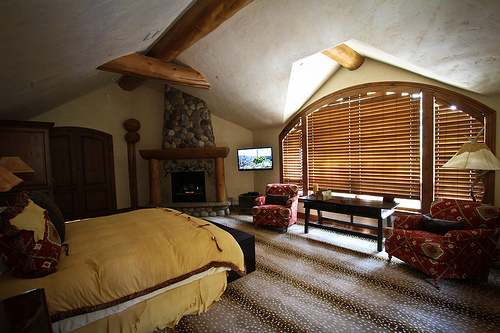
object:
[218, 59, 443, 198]
wall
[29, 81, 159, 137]
wall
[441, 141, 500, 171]
lampshade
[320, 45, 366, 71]
beam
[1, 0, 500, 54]
ceiling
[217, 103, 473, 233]
indoors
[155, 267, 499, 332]
carpet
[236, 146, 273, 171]
tv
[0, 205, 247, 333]
bed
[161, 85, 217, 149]
chimney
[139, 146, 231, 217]
fireplace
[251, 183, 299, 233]
sofa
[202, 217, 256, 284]
container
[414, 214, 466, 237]
pillow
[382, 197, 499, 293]
chair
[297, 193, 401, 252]
table